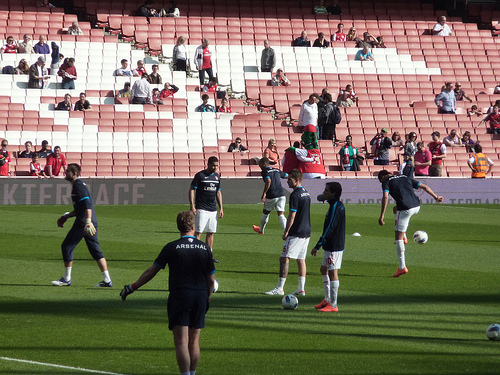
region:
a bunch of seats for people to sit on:
[3, 4, 498, 181]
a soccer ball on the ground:
[277, 288, 301, 310]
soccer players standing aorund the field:
[55, 155, 442, 367]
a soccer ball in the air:
[404, 225, 429, 248]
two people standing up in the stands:
[293, 93, 337, 137]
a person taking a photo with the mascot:
[282, 125, 324, 177]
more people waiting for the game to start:
[384, 131, 494, 176]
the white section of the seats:
[29, 41, 445, 87]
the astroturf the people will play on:
[0, 203, 498, 374]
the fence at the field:
[5, 178, 499, 203]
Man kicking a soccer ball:
[375, 169, 445, 276]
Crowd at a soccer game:
[117, 55, 180, 107]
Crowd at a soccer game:
[292, 22, 386, 62]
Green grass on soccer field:
[41, 309, 118, 354]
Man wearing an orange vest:
[465, 144, 495, 178]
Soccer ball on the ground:
[280, 291, 301, 309]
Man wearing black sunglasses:
[229, 138, 248, 151]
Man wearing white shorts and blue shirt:
[312, 179, 346, 316]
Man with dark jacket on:
[257, 40, 277, 72]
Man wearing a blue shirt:
[436, 80, 458, 114]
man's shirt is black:
[155, 238, 228, 319]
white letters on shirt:
[163, 240, 213, 257]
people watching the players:
[3, 5, 496, 189]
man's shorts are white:
[278, 229, 323, 277]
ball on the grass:
[264, 278, 316, 323]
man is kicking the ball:
[371, 152, 461, 291]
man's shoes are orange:
[313, 298, 351, 329]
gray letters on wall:
[6, 178, 153, 208]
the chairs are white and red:
[0, 4, 498, 182]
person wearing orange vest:
[463, 153, 492, 182]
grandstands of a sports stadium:
[3, 5, 499, 172]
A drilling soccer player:
[369, 165, 447, 285]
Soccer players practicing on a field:
[187, 155, 452, 311]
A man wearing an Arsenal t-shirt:
[113, 203, 227, 371]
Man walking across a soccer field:
[37, 159, 115, 293]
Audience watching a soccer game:
[338, 125, 499, 280]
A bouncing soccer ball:
[412, 228, 430, 245]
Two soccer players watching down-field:
[264, 167, 361, 324]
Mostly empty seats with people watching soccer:
[3, 18, 499, 139]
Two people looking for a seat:
[163, 28, 225, 83]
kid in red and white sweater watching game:
[29, 152, 46, 177]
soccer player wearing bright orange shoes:
[308, 181, 349, 313]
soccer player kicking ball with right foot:
[375, 169, 445, 280]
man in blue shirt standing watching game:
[436, 82, 458, 117]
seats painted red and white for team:
[393, 46, 449, 77]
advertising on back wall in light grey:
[0, 177, 147, 205]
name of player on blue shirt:
[172, 242, 210, 252]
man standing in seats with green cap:
[369, 126, 391, 165]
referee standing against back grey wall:
[467, 144, 492, 179]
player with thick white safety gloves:
[83, 204, 95, 239]